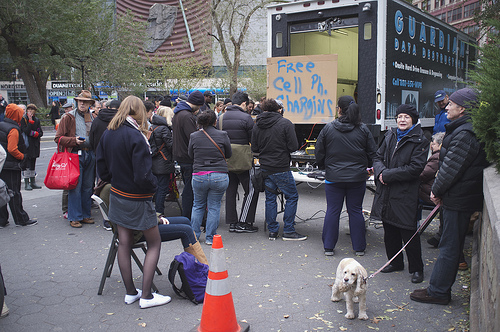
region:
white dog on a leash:
[322, 243, 377, 330]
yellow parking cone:
[192, 230, 249, 330]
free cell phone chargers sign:
[267, 50, 344, 122]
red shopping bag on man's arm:
[44, 146, 83, 191]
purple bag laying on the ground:
[167, 250, 212, 300]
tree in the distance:
[5, 0, 128, 75]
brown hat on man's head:
[70, 86, 95, 100]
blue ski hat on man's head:
[450, 85, 479, 106]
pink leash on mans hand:
[355, 195, 445, 269]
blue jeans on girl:
[185, 169, 240, 229]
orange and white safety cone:
[188, 228, 250, 328]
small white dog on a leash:
[311, 195, 456, 316]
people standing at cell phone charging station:
[32, 66, 385, 207]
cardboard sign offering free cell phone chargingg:
[251, 50, 343, 128]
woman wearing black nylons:
[115, 195, 169, 305]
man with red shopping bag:
[47, 88, 92, 216]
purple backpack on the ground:
[158, 241, 215, 306]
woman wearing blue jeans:
[182, 167, 234, 241]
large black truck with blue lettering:
[255, 1, 484, 178]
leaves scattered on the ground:
[284, 214, 464, 324]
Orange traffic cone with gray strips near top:
[180, 232, 263, 331]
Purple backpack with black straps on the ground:
[163, 247, 204, 307]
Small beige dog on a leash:
[330, 205, 430, 315]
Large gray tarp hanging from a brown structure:
[108, 0, 205, 70]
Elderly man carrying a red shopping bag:
[45, 85, 95, 225]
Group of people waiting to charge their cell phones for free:
[5, 45, 360, 306]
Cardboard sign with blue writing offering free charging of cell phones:
[266, 58, 336, 124]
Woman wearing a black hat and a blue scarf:
[368, 101, 426, 282]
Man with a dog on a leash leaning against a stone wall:
[327, 85, 495, 330]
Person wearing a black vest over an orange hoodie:
[1, 102, 50, 230]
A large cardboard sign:
[264, 54, 336, 125]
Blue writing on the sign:
[273, 59, 333, 121]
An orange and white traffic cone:
[187, 233, 254, 330]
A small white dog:
[327, 255, 371, 320]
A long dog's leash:
[364, 202, 440, 279]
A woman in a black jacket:
[186, 109, 233, 245]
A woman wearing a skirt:
[95, 93, 173, 307]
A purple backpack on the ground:
[167, 252, 210, 306]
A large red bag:
[44, 134, 81, 192]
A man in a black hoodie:
[249, 99, 309, 241]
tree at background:
[0, 2, 67, 97]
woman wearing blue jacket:
[108, 133, 148, 193]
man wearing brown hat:
[72, 90, 95, 101]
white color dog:
[336, 257, 368, 319]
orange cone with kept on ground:
[204, 233, 236, 328]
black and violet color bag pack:
[168, 248, 203, 301]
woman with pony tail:
[338, 96, 355, 117]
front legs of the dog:
[344, 294, 368, 319]